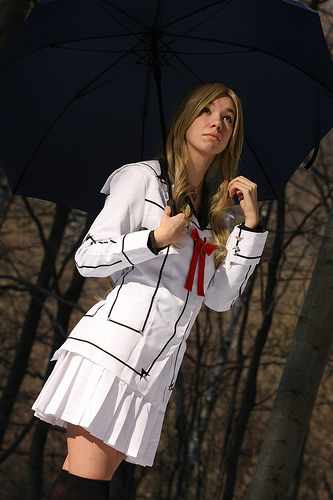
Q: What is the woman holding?
A: Umbrella.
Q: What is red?
A: Ribbon.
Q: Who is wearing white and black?
A: The woman.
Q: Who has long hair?
A: The woman.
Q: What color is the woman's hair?
A: Blonde.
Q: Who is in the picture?
A: A woman.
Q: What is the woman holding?
A: A umbrella.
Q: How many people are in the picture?
A: 1.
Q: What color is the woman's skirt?
A: White.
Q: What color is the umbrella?
A: Black.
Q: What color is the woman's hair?
A: Blonde.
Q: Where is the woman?
A: In the woods.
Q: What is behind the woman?
A: Trees.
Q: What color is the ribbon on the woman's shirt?
A: Red.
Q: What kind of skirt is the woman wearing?
A: Pleated.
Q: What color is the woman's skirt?
A: White.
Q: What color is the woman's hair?
A: Blonde.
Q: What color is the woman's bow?
A: Red.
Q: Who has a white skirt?
A: The woman.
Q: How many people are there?
A: One.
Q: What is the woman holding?
A: An umbrella.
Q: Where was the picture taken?
A: In the woods.